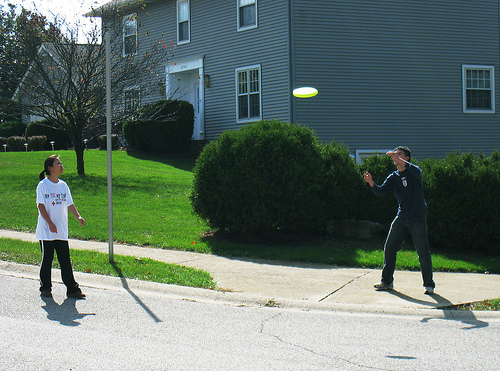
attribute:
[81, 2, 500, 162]
house — gray, big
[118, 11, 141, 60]
window — closed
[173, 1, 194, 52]
window — closed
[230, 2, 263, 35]
window — closed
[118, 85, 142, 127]
window — closed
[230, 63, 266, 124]
window — closed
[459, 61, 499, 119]
window — closed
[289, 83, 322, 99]
frisbee — yellow, round, airborne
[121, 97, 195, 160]
hedge — green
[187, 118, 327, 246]
hedge — green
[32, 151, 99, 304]
girl — standing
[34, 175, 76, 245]
shirt — white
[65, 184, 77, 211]
sleeve — short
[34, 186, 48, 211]
sleeve — short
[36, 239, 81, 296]
pants — black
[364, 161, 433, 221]
shirt — blue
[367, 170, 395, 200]
sleeve — long